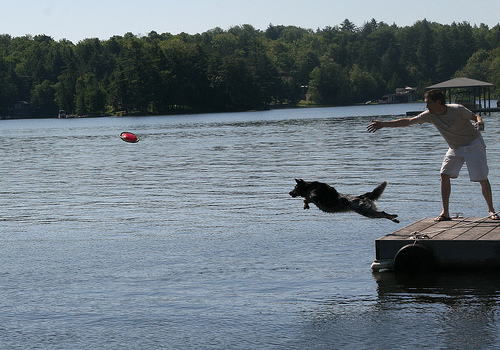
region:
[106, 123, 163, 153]
Red frisbee in the air.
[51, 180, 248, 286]
Calm blue lake water.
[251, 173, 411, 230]
Black dog jumping for the frisbee.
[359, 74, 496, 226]
Man tossing the frisbee.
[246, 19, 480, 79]
Pine trees in the background.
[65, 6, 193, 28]
Pale blue sky in the distance.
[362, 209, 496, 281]
A dock in the water.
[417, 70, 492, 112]
Wonderful place for a picnic.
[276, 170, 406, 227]
The black dog is named Scruffy.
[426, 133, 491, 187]
Man in cargo shorts.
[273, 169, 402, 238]
the dog in the air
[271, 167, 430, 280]
the dog jumping of the pier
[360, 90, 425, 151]
the arm of the man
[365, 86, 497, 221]
the man throwing a frisbee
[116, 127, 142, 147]
the red frisbee in the air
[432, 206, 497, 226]
the sandals on the mans feet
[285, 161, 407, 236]
the black dog jumping into the water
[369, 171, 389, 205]
the tail of the dog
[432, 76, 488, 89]
the roof of the gondela on the pier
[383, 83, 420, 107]
a house on the otherside of the water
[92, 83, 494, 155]
man throwing frisbee over water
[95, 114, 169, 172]
red frisbee above lake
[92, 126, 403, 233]
dog jumping after frisbee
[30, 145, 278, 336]
calm lake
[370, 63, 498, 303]
man on wooden dock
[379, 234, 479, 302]
inner tube at end of dock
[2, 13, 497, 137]
tree line on shore across lake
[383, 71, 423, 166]
house on far shore of lake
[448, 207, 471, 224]
thing to tie boats to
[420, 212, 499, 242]
rope across dock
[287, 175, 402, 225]
a black dog jumping into the water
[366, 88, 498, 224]
a man standing on a wooden dock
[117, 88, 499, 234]
a man throwing a red disk into the air for the dog to catch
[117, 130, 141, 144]
a red and black disk in the air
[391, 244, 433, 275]
a black tube on the side of the bench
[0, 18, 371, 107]
tall green trees beside the river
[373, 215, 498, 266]
a wooden deck on the water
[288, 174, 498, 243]
a black dog jumping off a deck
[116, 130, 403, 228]
a black dog jumping after the red disk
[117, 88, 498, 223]
a pet-owner playing Frisbee with a dog on a river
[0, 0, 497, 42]
pale blue of sky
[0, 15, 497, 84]
tree tops in daylight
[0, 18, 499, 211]
trees facing water surface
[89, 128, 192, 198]
red frisbee over water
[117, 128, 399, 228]
dog jumping toward frisbee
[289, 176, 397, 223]
body of jumping dog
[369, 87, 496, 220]
man with extended arm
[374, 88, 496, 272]
man standing on dock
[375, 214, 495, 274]
tire on side of dock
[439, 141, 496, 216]
white shorts on legs